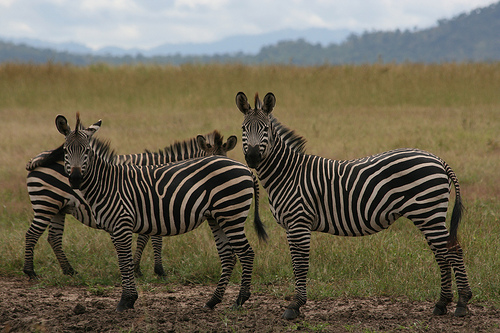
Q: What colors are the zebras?
A: White and black.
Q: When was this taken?
A: During the day.